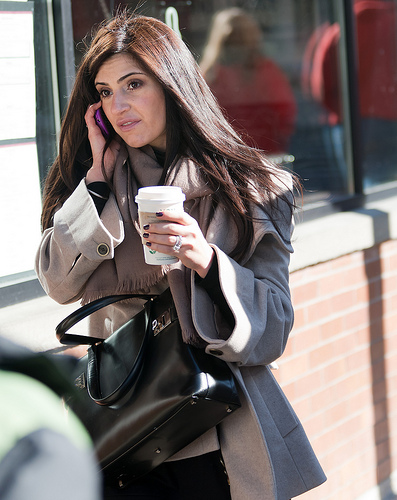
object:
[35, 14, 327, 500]
woman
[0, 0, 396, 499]
building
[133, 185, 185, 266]
coffee cup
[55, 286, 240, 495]
handbag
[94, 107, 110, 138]
cell phone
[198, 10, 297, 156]
reflection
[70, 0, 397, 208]
window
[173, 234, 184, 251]
ring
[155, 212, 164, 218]
fingernails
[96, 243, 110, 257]
button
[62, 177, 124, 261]
coat cuff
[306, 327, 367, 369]
bricks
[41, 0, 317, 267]
hair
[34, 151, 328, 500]
coat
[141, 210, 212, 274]
hand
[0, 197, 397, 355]
ledge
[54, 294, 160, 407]
handle